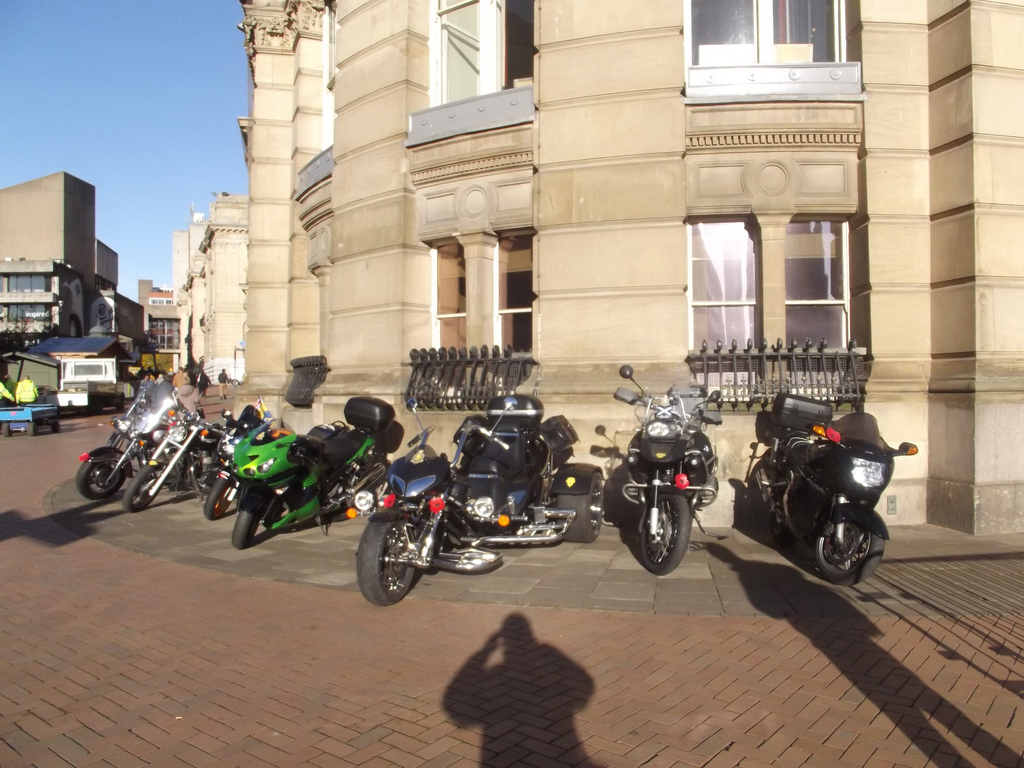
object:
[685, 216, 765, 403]
window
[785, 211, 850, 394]
window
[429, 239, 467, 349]
window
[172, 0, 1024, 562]
building